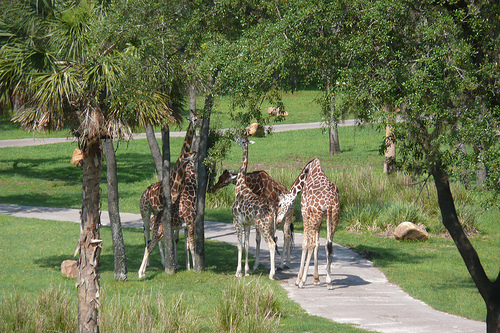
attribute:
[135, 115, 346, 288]
giraffes — walking, grouped, covered, wandering, eating, five, plenty, grazing, enclosed, standing, wildlife, brown, white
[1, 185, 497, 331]
sidewalk — white, cement, gray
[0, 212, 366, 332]
grass — green, tall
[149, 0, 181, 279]
tree — small, barked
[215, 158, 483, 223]
bushes — green, brown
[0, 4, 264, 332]
trees — shady, green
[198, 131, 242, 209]
leaves — green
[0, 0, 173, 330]
tree — palm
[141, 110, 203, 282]
giraffe — here, brown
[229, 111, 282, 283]
giraffe — here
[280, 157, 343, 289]
giraffe — here, smelling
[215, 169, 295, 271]
giraffe — here, smelled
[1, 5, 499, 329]
park — wild, beautiful, landscaped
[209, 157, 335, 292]
giraffes — brown, white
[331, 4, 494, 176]
leaves — green, dry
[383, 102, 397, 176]
trunk — brown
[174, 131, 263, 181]
necks — long